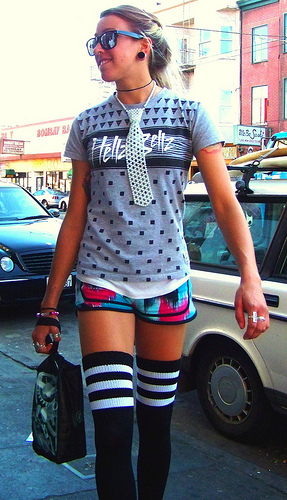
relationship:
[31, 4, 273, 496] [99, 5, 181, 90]
woman has hair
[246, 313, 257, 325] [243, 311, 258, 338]
ring on finger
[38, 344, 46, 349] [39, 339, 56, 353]
ring on finger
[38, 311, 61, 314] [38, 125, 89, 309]
bracelet on arm